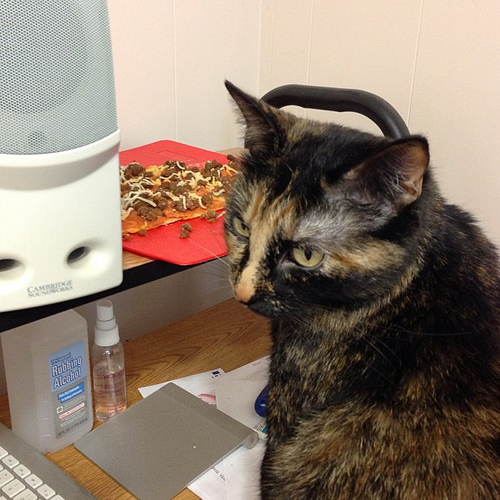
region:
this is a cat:
[209, 58, 499, 493]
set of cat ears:
[197, 62, 448, 213]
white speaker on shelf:
[8, 4, 160, 364]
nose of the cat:
[225, 243, 273, 319]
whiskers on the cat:
[178, 235, 418, 366]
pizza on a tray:
[102, 123, 260, 293]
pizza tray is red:
[98, 110, 258, 288]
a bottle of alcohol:
[0, 306, 116, 457]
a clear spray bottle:
[82, 296, 144, 432]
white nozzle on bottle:
[88, 296, 127, 356]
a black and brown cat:
[181, 68, 493, 496]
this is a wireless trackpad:
[57, 383, 315, 498]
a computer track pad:
[55, 369, 270, 499]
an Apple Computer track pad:
[50, 377, 262, 499]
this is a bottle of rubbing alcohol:
[8, 315, 101, 459]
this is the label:
[42, 337, 113, 444]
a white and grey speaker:
[2, 0, 140, 314]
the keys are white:
[4, 457, 43, 499]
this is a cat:
[195, 68, 498, 493]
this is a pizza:
[122, 130, 239, 250]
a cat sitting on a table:
[220, 80, 497, 495]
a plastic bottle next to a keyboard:
[0, 310, 90, 451]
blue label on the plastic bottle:
[47, 340, 84, 390]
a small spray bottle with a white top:
[90, 300, 122, 421]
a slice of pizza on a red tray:
[120, 157, 235, 232]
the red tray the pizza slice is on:
[120, 140, 240, 265]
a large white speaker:
[0, 0, 120, 310]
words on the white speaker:
[25, 280, 75, 300]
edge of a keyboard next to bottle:
[0, 420, 95, 495]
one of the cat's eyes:
[282, 235, 329, 271]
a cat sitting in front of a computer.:
[210, 70, 498, 497]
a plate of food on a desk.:
[106, 95, 295, 292]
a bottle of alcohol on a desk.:
[4, 288, 103, 453]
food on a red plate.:
[115, 144, 247, 245]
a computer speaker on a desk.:
[0, 1, 132, 321]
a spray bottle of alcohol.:
[89, 292, 141, 430]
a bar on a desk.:
[229, 58, 449, 152]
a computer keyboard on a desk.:
[0, 412, 86, 498]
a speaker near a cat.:
[3, 5, 147, 304]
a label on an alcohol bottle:
[43, 328, 90, 446]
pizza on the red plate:
[123, 144, 242, 224]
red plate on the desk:
[121, 130, 263, 265]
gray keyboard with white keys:
[5, 418, 88, 499]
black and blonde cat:
[222, 82, 492, 499]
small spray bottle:
[90, 298, 125, 417]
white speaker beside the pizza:
[0, 5, 137, 295]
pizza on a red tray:
[117, 121, 243, 281]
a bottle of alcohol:
[2, 310, 99, 468]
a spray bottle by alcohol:
[92, 297, 133, 421]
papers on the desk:
[156, 334, 271, 496]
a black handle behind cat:
[253, 53, 423, 136]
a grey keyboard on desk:
[2, 417, 97, 499]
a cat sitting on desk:
[186, 73, 498, 497]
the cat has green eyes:
[207, 217, 342, 274]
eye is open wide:
[283, 226, 347, 278]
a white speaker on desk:
[1, 0, 135, 338]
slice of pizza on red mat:
[105, 150, 258, 235]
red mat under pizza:
[108, 134, 274, 281]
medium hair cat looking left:
[206, 74, 498, 499]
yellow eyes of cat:
[218, 205, 332, 272]